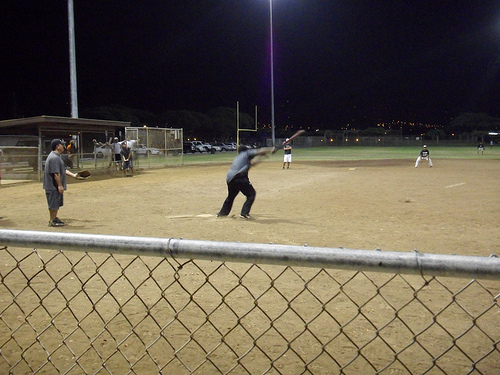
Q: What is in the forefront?
A: Chain link fence.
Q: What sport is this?
A: Baseball.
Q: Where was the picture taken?
A: At the basketball field.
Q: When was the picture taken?
A: At night.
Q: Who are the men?
A: Basketball players.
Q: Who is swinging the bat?
A: A man in the black pants.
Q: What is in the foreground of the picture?
A: Chain link fence.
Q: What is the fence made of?
A: Metal.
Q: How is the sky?
A: Very dark.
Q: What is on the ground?
A: Dirt.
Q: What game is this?
A: Baseball.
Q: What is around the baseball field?
A: A fence.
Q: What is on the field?
A: Grass.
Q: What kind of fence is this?
A: A chain link fence.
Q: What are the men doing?
A: Playing baseball.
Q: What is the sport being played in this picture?
A: Baseball field.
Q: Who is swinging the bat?
A: The hitter.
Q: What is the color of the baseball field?
A: Brown.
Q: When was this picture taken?
A: Nighttime.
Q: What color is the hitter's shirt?
A: Blue.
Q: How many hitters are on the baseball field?
A: One.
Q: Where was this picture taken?
A: A baseball field.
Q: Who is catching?
A: A man.